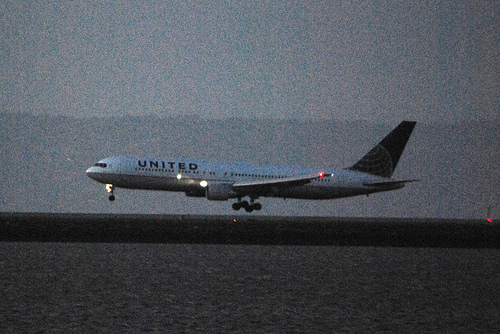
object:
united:
[136, 159, 196, 169]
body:
[84, 156, 405, 200]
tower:
[482, 201, 497, 224]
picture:
[1, 0, 500, 333]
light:
[486, 216, 494, 224]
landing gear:
[103, 183, 114, 192]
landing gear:
[236, 195, 243, 200]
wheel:
[231, 203, 239, 211]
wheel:
[238, 199, 248, 207]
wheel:
[243, 204, 256, 214]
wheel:
[251, 202, 265, 213]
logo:
[355, 145, 396, 178]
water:
[0, 241, 500, 333]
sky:
[0, 0, 500, 219]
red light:
[317, 170, 327, 176]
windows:
[133, 166, 138, 171]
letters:
[135, 158, 145, 168]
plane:
[86, 118, 420, 212]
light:
[196, 179, 212, 187]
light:
[175, 173, 183, 181]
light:
[103, 183, 115, 193]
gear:
[106, 194, 116, 202]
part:
[341, 117, 418, 176]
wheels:
[107, 193, 113, 203]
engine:
[205, 186, 236, 202]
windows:
[146, 166, 150, 171]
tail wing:
[345, 119, 415, 177]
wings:
[360, 177, 428, 183]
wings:
[229, 172, 338, 188]